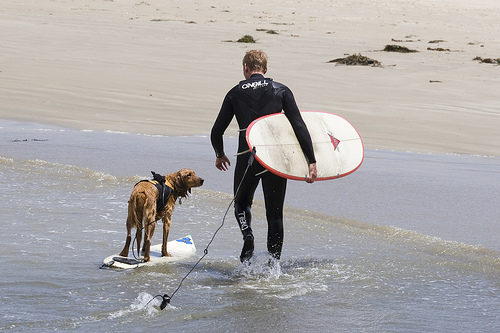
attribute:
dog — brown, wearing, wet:
[120, 167, 205, 259]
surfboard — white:
[98, 232, 202, 275]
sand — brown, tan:
[1, 2, 499, 332]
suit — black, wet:
[210, 78, 318, 261]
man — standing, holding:
[210, 49, 316, 269]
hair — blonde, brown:
[243, 49, 270, 74]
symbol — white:
[243, 79, 273, 94]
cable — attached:
[132, 148, 257, 307]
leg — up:
[231, 178, 287, 270]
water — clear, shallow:
[5, 123, 496, 331]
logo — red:
[329, 130, 339, 151]